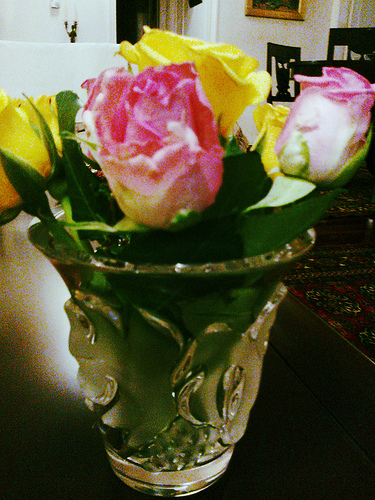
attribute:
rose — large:
[77, 65, 236, 224]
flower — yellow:
[269, 61, 362, 176]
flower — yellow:
[72, 57, 251, 224]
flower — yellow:
[1, 73, 75, 212]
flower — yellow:
[133, 26, 272, 131]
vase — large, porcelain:
[42, 218, 311, 495]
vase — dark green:
[26, 196, 321, 499]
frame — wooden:
[246, 0, 309, 21]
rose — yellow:
[2, 86, 60, 219]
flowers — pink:
[276, 67, 374, 185]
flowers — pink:
[81, 61, 221, 224]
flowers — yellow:
[117, 24, 271, 144]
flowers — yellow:
[249, 102, 289, 178]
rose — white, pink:
[282, 58, 373, 176]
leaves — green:
[227, 136, 367, 239]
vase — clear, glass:
[33, 223, 371, 478]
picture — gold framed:
[243, 0, 307, 24]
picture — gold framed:
[264, 40, 303, 103]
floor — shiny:
[308, 214, 374, 249]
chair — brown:
[316, 17, 373, 79]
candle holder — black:
[62, 19, 80, 47]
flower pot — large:
[22, 225, 322, 492]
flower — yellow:
[0, 90, 65, 212]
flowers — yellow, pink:
[2, 19, 373, 241]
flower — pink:
[274, 65, 374, 188]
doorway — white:
[132, 7, 155, 27]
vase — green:
[66, 245, 282, 337]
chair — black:
[263, 41, 303, 114]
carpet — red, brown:
[315, 254, 371, 317]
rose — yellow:
[114, 23, 205, 69]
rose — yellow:
[190, 37, 274, 142]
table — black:
[50, 190, 369, 466]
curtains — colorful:
[156, 0, 190, 40]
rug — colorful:
[268, 197, 370, 456]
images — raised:
[63, 280, 289, 453]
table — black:
[9, 209, 373, 498]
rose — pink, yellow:
[81, 69, 222, 231]